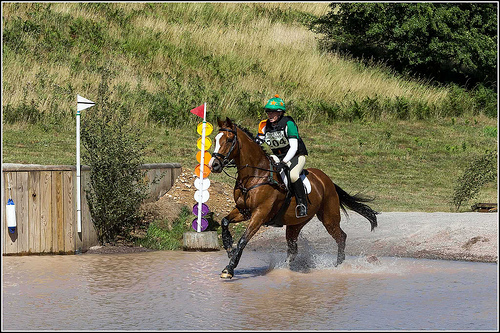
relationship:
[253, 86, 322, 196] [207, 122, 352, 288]
rider on horse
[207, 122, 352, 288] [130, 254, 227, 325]
horse on water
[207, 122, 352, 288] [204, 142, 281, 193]
horse has harness